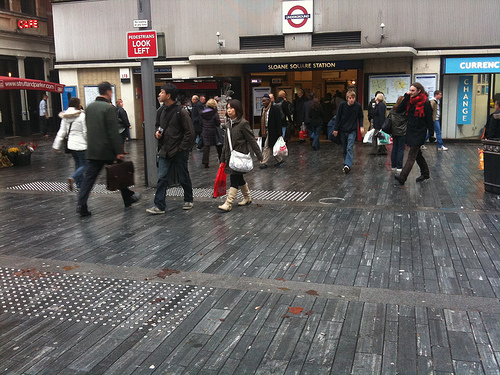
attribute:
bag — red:
[205, 158, 235, 205]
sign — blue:
[451, 71, 478, 125]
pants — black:
[149, 156, 195, 214]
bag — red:
[209, 161, 229, 202]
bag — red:
[210, 161, 227, 198]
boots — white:
[214, 185, 239, 217]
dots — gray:
[71, 273, 151, 311]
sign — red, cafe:
[14, 15, 40, 29]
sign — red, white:
[185, 93, 272, 195]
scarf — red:
[408, 97, 428, 119]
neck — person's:
[411, 93, 426, 100]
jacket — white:
[51, 105, 92, 152]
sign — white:
[282, 1, 314, 34]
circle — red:
[286, 2, 309, 27]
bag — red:
[209, 156, 227, 195]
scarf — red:
[404, 95, 430, 114]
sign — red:
[118, 26, 163, 66]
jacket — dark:
[259, 100, 283, 144]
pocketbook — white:
[227, 147, 257, 175]